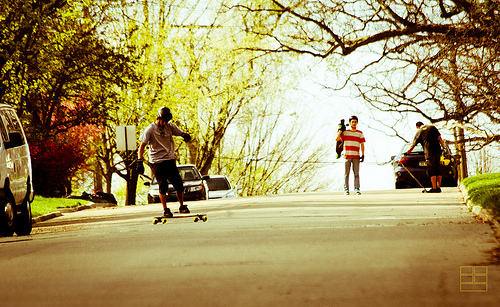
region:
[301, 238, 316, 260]
part f a road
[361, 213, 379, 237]
a[prt of a line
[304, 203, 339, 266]
part f a line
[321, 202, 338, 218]
part fo a liner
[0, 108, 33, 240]
white van in street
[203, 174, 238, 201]
car parked in street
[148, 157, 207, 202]
vehicle parked in street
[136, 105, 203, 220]
skater skating in street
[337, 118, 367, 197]
skater standing in street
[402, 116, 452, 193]
skater standing in street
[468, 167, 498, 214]
green grass by skater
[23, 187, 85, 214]
green grass by street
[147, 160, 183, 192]
black shorts of skater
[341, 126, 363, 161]
red and white shirt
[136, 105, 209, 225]
Man riding a skateboard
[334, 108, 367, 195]
Man holding a skateboard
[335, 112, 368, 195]
Man wearing red and white striped shirt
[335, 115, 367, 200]
Man wearing khaki pants and black gloves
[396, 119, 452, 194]
Man standing on the side of a road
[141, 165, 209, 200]
Black car parked on the side of a street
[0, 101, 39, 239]
White utility van parked on the side of a road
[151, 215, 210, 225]
Yellow wheels on a skateboard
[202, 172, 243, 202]
White SUV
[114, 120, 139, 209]
Metal pole and sign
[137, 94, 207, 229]
man on skateboard in street.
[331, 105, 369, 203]
man in red and white striped shirt.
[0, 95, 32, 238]
White van parked on side of street.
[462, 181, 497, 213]
patch of grass on side of cement.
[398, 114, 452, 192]
boy holding skateboard sideways.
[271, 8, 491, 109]
Large tree branches hanging over street..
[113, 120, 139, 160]
Back part of street sign.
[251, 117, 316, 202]
Trees peaking out from down hill.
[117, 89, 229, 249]
person on skateboard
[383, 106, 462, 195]
man standing in street in front of car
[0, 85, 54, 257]
van parked beside street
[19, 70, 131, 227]
red tree behind van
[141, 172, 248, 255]
skateboard with yellow wheels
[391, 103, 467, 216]
man holding yellow helmet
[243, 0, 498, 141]
long tree branches above street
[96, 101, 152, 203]
white sign behind stater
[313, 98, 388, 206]
man holding skateboard at his side